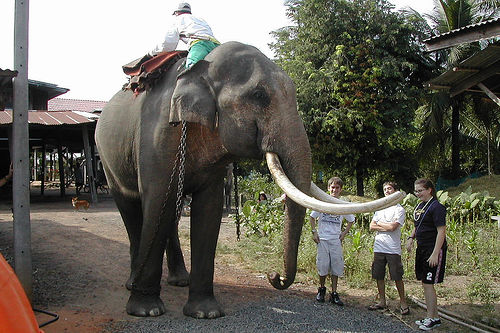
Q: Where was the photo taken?
A: It was taken at the field.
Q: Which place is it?
A: It is a field.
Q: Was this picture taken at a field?
A: Yes, it was taken in a field.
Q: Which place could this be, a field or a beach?
A: It is a field.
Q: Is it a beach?
A: No, it is a field.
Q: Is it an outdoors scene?
A: Yes, it is outdoors.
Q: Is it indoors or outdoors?
A: It is outdoors.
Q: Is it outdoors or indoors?
A: It is outdoors.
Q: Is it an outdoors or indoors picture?
A: It is outdoors.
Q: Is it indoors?
A: No, it is outdoors.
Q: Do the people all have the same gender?
A: No, they are both male and female.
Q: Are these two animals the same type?
A: No, they are dogs and elephants.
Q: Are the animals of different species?
A: Yes, they are dogs and elephants.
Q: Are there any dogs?
A: Yes, there is a dog.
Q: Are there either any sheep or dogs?
A: Yes, there is a dog.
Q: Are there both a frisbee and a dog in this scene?
A: No, there is a dog but no frisbees.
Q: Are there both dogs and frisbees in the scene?
A: No, there is a dog but no frisbees.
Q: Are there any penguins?
A: No, there are no penguins.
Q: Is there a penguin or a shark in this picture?
A: No, there are no penguins or sharks.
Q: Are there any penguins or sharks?
A: No, there are no penguins or sharks.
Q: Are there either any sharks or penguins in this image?
A: No, there are no penguins or sharks.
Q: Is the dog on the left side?
A: Yes, the dog is on the left of the image.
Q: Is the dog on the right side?
A: No, the dog is on the left of the image.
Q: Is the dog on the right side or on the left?
A: The dog is on the left of the image.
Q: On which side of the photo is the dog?
A: The dog is on the left of the image.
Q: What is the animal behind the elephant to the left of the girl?
A: The animal is a dog.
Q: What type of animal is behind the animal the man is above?
A: The animal is a dog.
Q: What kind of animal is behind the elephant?
A: The animal is a dog.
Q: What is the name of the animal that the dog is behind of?
A: The animal is an elephant.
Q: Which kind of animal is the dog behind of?
A: The dog is behind the elephant.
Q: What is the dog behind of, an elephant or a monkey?
A: The dog is behind an elephant.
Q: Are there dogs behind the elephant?
A: Yes, there is a dog behind the elephant.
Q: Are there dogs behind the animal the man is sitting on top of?
A: Yes, there is a dog behind the elephant.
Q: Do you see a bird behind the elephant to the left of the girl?
A: No, there is a dog behind the elephant.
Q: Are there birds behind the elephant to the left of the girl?
A: No, there is a dog behind the elephant.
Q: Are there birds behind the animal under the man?
A: No, there is a dog behind the elephant.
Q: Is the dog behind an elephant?
A: Yes, the dog is behind an elephant.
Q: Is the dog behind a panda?
A: No, the dog is behind an elephant.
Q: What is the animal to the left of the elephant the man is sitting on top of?
A: The animal is a dog.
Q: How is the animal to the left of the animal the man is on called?
A: The animal is a dog.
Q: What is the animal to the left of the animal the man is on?
A: The animal is a dog.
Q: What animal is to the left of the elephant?
A: The animal is a dog.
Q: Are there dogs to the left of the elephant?
A: Yes, there is a dog to the left of the elephant.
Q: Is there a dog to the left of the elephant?
A: Yes, there is a dog to the left of the elephant.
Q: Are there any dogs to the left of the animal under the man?
A: Yes, there is a dog to the left of the elephant.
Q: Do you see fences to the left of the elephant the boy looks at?
A: No, there is a dog to the left of the elephant.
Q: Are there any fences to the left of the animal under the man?
A: No, there is a dog to the left of the elephant.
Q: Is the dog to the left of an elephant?
A: Yes, the dog is to the left of an elephant.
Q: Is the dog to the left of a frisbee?
A: No, the dog is to the left of an elephant.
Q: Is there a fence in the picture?
A: No, there are no fences.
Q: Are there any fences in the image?
A: No, there are no fences.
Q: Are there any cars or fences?
A: No, there are no fences or cars.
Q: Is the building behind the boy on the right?
A: Yes, the building is behind the boy.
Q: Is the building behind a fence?
A: No, the building is behind the boy.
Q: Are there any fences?
A: No, there are no fences.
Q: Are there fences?
A: No, there are no fences.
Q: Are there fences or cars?
A: No, there are no fences or cars.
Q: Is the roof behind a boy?
A: Yes, the roof is behind a boy.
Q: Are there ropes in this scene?
A: No, there are no ropes.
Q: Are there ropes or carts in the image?
A: No, there are no ropes or carts.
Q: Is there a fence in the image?
A: No, there are no fences.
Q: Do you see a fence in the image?
A: No, there are no fences.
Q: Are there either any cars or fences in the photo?
A: No, there are no fences or cars.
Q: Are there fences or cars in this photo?
A: No, there are no fences or cars.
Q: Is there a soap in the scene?
A: No, there are no soaps.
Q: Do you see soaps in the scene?
A: No, there are no soaps.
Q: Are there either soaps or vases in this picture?
A: No, there are no soaps or vases.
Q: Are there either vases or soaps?
A: No, there are no soaps or vases.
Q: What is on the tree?
A: The leaves are on the tree.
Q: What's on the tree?
A: The leaves are on the tree.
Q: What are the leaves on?
A: The leaves are on the tree.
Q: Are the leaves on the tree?
A: Yes, the leaves are on the tree.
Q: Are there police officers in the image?
A: No, there are no police officers.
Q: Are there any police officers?
A: No, there are no police officers.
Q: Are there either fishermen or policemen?
A: No, there are no policemen or fishermen.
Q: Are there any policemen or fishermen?
A: No, there are no policemen or fishermen.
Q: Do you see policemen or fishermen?
A: No, there are no policemen or fishermen.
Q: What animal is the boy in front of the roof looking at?
A: The boy is looking at the elephant.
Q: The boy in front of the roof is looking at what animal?
A: The boy is looking at the elephant.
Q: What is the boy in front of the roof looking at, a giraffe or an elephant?
A: The boy is looking at an elephant.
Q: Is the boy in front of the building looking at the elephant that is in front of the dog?
A: Yes, the boy is looking at the elephant.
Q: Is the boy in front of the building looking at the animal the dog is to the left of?
A: Yes, the boy is looking at the elephant.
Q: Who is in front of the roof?
A: The boy is in front of the roof.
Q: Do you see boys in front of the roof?
A: Yes, there is a boy in front of the roof.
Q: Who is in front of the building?
A: The boy is in front of the building.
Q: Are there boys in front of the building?
A: Yes, there is a boy in front of the building.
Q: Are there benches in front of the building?
A: No, there is a boy in front of the building.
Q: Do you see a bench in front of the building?
A: No, there is a boy in front of the building.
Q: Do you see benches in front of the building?
A: No, there is a boy in front of the building.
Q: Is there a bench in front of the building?
A: No, there is a boy in front of the building.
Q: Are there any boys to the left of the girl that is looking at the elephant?
A: Yes, there is a boy to the left of the girl.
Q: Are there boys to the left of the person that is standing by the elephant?
A: Yes, there is a boy to the left of the girl.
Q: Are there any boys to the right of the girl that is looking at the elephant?
A: No, the boy is to the left of the girl.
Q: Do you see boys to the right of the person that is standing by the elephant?
A: No, the boy is to the left of the girl.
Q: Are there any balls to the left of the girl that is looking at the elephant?
A: No, there is a boy to the left of the girl.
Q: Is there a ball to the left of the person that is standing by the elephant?
A: No, there is a boy to the left of the girl.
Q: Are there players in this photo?
A: No, there are no players.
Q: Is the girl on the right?
A: Yes, the girl is on the right of the image.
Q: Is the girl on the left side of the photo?
A: No, the girl is on the right of the image.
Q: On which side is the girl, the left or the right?
A: The girl is on the right of the image.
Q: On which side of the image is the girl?
A: The girl is on the right of the image.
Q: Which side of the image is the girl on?
A: The girl is on the right of the image.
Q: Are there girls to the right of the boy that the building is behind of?
A: Yes, there is a girl to the right of the boy.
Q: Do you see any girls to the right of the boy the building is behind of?
A: Yes, there is a girl to the right of the boy.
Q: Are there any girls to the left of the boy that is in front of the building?
A: No, the girl is to the right of the boy.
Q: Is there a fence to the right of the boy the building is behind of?
A: No, there is a girl to the right of the boy.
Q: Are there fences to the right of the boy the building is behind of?
A: No, there is a girl to the right of the boy.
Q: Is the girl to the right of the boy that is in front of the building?
A: Yes, the girl is to the right of the boy.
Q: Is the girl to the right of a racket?
A: No, the girl is to the right of the boy.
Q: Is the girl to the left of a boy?
A: No, the girl is to the right of a boy.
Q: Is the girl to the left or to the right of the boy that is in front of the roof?
A: The girl is to the right of the boy.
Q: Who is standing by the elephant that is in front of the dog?
A: The girl is standing by the elephant.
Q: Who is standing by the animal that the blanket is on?
A: The girl is standing by the elephant.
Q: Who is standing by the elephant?
A: The girl is standing by the elephant.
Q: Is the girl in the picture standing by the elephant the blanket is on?
A: Yes, the girl is standing by the elephant.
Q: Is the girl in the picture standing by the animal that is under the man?
A: Yes, the girl is standing by the elephant.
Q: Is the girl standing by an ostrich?
A: No, the girl is standing by the elephant.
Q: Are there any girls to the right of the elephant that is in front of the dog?
A: Yes, there is a girl to the right of the elephant.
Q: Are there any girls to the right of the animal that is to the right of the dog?
A: Yes, there is a girl to the right of the elephant.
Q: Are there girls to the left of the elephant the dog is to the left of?
A: No, the girl is to the right of the elephant.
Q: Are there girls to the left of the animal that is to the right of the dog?
A: No, the girl is to the right of the elephant.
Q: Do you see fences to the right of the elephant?
A: No, there is a girl to the right of the elephant.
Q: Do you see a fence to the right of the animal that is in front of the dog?
A: No, there is a girl to the right of the elephant.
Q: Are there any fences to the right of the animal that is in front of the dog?
A: No, there is a girl to the right of the elephant.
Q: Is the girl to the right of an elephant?
A: Yes, the girl is to the right of an elephant.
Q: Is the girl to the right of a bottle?
A: No, the girl is to the right of an elephant.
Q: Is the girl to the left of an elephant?
A: No, the girl is to the right of an elephant.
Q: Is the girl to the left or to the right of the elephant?
A: The girl is to the right of the elephant.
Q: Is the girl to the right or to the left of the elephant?
A: The girl is to the right of the elephant.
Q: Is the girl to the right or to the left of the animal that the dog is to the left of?
A: The girl is to the right of the elephant.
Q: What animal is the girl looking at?
A: The girl is looking at the elephant.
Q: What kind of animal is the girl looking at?
A: The girl is looking at the elephant.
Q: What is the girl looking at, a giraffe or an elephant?
A: The girl is looking at an elephant.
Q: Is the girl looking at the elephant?
A: Yes, the girl is looking at the elephant.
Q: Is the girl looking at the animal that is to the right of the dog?
A: Yes, the girl is looking at the elephant.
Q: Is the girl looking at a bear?
A: No, the girl is looking at the elephant.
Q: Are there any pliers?
A: No, there are no pliers.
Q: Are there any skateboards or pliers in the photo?
A: No, there are no pliers or skateboards.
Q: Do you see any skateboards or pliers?
A: No, there are no pliers or skateboards.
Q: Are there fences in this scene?
A: No, there are no fences.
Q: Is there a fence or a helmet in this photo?
A: No, there are no fences or helmets.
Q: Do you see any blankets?
A: Yes, there is a blanket.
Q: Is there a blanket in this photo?
A: Yes, there is a blanket.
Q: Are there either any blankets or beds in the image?
A: Yes, there is a blanket.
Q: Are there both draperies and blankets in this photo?
A: No, there is a blanket but no drapes.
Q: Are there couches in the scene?
A: No, there are no couches.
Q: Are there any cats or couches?
A: No, there are no couches or cats.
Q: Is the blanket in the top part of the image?
A: Yes, the blanket is in the top of the image.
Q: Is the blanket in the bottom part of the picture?
A: No, the blanket is in the top of the image.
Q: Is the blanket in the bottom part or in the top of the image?
A: The blanket is in the top of the image.